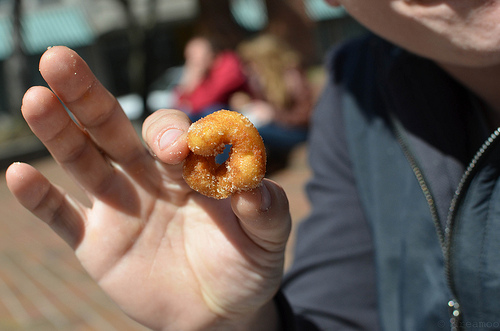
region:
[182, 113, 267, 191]
a small fried shrimp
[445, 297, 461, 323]
a blurry metal zipper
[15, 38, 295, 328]
a man holding a fried shrimp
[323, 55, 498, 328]
a gray and blue jacket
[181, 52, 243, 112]
a blurry red coat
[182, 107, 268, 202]
a coconut shrimp puff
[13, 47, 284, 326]
a mans hand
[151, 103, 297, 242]
a fried treat in a mans fingers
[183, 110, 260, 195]
a white flaky treat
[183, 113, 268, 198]
tiny round doughnut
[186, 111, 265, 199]
sugar-covered fried dough ring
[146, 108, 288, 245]
doughnut between thumb and index finger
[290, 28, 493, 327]
a gray jacket with a zipper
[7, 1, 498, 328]
man holding a tiny doughnut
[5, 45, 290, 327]
a hand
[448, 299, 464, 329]
zipper pull on zipper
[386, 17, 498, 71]
the man's chin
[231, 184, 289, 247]
the man's thumb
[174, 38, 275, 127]
someone in background in a red shirt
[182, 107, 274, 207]
tiny round golden donut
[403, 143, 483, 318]
person with zippered jacket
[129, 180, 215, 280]
lines on palm of mans hand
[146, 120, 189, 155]
person with very short fingernails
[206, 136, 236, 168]
whole in the center of tiny donut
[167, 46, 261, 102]
person in red shirt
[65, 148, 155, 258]
shadow on mans hand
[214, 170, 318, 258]
man with his thumb bent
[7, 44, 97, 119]
man with sun shining on fingertips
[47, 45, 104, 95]
sugar on finger of man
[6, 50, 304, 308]
hand of a person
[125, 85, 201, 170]
finger of a person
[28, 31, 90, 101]
finger of a person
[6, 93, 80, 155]
finger of a person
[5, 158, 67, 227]
finger of a person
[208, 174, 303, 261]
thumb of a person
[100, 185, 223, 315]
palm of a person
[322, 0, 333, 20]
ear of a person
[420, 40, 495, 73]
jaw of a person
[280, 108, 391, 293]
arm of a person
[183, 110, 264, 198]
Small shrimp shaped doughnut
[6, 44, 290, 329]
Hand holding a doughnut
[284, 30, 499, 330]
Dark blue jacket with zipper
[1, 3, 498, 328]
Man showing off an oddly shaped doughnut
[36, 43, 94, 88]
Tip of a finger with sugar on it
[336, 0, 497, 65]
Half of a man's chin and jaw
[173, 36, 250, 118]
Person wearing red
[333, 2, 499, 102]
Part of a shadowed face and neck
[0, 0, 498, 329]
Man in a blue jacket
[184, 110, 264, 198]
Brown sugar covered piece of fried dough